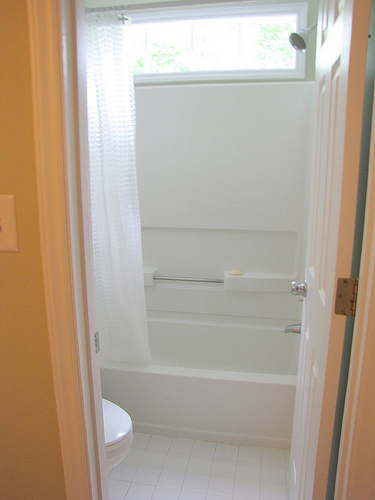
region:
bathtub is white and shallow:
[82, 305, 317, 467]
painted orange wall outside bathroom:
[12, 40, 50, 368]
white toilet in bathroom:
[106, 401, 142, 484]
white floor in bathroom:
[151, 443, 271, 493]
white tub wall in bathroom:
[119, 364, 284, 436]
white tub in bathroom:
[156, 301, 281, 421]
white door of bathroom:
[299, 97, 339, 451]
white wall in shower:
[142, 100, 294, 218]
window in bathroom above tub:
[139, 27, 287, 69]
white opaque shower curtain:
[87, 24, 180, 336]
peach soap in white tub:
[214, 258, 257, 286]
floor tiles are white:
[125, 432, 284, 498]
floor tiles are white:
[150, 452, 261, 496]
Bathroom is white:
[54, 2, 369, 498]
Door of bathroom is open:
[270, 2, 373, 492]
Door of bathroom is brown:
[278, 0, 371, 499]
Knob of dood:
[282, 275, 310, 305]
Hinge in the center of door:
[325, 258, 373, 324]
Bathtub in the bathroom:
[105, 298, 300, 449]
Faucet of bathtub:
[277, 316, 305, 346]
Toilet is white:
[100, 387, 142, 487]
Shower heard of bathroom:
[275, 5, 323, 81]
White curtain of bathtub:
[81, 7, 167, 379]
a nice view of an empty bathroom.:
[45, 42, 355, 493]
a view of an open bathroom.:
[54, 12, 354, 481]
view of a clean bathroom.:
[46, 4, 349, 469]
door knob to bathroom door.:
[285, 272, 308, 308]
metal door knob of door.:
[285, 270, 311, 304]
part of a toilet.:
[78, 390, 157, 466]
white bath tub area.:
[128, 294, 274, 429]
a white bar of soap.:
[225, 261, 250, 279]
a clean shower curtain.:
[84, 0, 170, 370]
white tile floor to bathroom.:
[127, 451, 257, 492]